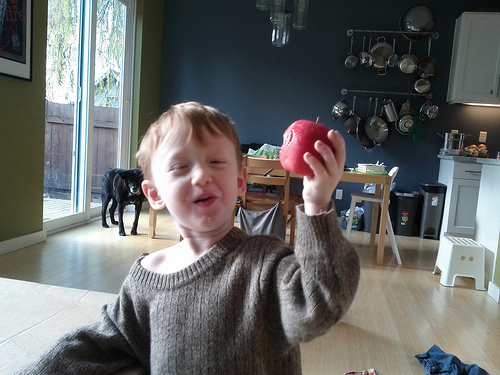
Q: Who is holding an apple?
A: The little boy.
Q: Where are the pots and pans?
A: Hanging on the wall.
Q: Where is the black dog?
A: Near the sliding doors.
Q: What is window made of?
A: Glass.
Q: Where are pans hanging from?
A: Wall.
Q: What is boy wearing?
A: Gray sweater.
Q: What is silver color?
A: Pots and pans.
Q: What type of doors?
A: Sliding.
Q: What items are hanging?
A: Pots and pans.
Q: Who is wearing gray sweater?
A: A kid.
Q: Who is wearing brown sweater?
A: A boy.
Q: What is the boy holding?
A: An apple.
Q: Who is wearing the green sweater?
A: The boy.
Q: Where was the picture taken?
A: In a house.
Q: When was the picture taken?
A: Daytime.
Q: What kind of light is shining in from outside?
A: Sunlight.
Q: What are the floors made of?
A: Wood.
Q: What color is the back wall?
A: Blue.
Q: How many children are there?
A: One.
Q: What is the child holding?
A: An apple.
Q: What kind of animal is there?
A: A dog.